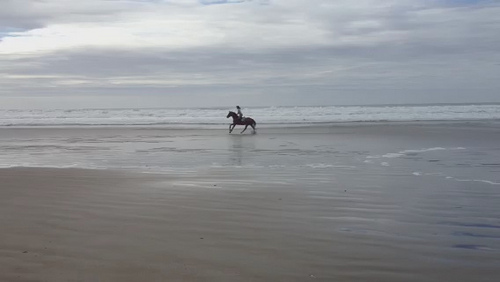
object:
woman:
[235, 105, 243, 119]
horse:
[226, 110, 258, 134]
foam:
[0, 100, 500, 126]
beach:
[0, 137, 500, 282]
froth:
[366, 146, 466, 158]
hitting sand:
[0, 165, 500, 282]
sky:
[0, 0, 500, 112]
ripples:
[312, 163, 500, 282]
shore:
[0, 164, 500, 282]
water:
[0, 103, 500, 170]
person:
[235, 106, 244, 120]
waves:
[0, 102, 500, 148]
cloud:
[0, 0, 500, 63]